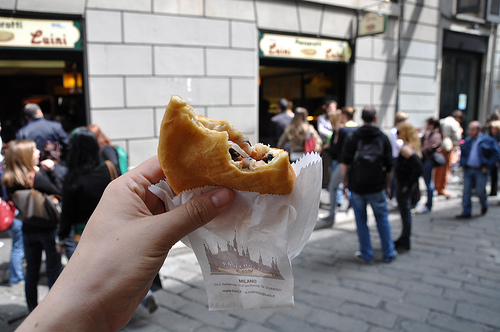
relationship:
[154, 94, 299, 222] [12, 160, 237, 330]
empanada held by person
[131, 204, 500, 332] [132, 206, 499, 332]
street made of cobblestones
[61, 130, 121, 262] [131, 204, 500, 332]
person on street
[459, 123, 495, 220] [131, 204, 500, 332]
person on street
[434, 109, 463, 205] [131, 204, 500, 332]
person on street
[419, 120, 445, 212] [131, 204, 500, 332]
person on street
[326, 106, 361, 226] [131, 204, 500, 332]
person on street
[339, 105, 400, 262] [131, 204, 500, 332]
man on street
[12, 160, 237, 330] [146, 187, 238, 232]
person has thumb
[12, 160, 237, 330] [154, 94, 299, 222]
person holding food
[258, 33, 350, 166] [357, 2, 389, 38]
business has sign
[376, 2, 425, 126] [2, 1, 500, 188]
shadow on building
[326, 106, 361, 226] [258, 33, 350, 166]
person entering restaurant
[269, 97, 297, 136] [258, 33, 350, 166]
person entering restaurant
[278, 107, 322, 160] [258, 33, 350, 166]
person entering restaurant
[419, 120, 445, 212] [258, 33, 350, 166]
person entering restaurant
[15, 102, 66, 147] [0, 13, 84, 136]
person entering restaurant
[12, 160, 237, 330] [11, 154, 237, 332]
person has person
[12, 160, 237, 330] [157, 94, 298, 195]
person holding empanada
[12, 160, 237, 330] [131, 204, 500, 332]
person in street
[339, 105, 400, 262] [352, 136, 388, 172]
person has backpack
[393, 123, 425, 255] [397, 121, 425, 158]
woman has hair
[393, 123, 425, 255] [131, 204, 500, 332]
woman in street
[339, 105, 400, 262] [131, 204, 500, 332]
person in street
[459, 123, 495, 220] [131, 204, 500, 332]
person in street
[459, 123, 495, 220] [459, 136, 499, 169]
person has coat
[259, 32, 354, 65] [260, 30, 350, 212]
sign in middle of doorway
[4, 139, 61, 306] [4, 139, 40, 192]
girl has hair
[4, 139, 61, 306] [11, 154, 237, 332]
girl left of person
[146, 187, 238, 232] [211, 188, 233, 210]
thumb has nail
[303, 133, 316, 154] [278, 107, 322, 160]
bag on right side of person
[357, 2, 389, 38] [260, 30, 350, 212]
sign above doorway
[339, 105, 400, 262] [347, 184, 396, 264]
person in blue jeans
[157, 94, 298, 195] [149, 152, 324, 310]
empanada wrapped in paper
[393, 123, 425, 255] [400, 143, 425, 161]
woman has bare shoulders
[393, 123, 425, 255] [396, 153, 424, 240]
woman in clothing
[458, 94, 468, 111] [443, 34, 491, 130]
sign on door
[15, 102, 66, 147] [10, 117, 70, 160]
person in coat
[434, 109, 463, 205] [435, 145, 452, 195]
person wearing pants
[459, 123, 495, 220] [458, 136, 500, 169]
person wearing coat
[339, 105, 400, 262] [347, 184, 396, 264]
person wearing blue jeans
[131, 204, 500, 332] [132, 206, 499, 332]
street made from brick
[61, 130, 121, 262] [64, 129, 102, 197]
person has hair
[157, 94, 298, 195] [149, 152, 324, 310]
empanada in bag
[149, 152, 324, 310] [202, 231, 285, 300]
bag has logo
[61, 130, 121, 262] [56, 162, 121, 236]
person wearing shirt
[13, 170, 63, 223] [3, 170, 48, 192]
bag around shoulder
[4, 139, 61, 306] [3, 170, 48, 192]
girl has shoulder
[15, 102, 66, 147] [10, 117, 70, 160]
person wearing coat